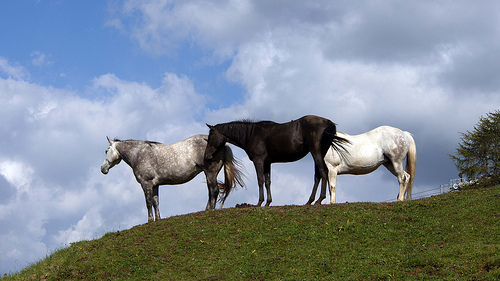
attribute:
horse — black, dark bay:
[201, 116, 336, 206]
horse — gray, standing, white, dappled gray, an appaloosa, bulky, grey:
[99, 130, 208, 219]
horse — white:
[336, 122, 422, 200]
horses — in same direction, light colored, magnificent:
[96, 118, 424, 210]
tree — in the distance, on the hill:
[442, 114, 498, 181]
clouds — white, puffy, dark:
[160, 13, 479, 112]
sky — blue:
[3, 3, 172, 83]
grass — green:
[141, 226, 481, 268]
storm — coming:
[264, 3, 499, 85]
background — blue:
[6, 5, 495, 111]